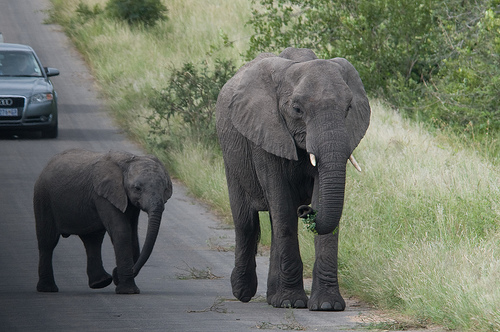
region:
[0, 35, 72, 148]
shiny silver audi driving on a paved road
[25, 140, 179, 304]
grey baby african elephant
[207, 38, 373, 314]
big grey african elephant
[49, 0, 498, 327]
tall light green grass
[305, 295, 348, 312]
grey curved elephant toes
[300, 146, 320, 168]
pointed white elephant tusk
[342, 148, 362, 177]
pointed white elephant tusk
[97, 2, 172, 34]
short green leafy bush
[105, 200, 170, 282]
baby elephant's wet trunk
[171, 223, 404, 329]
dead grass strewn on the road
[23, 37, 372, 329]
There are two elephants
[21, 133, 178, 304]
This is the smaller elephant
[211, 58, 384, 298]
This is the larger elephant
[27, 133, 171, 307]
Smaller elephant is in the middle of the road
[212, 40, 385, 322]
Larger elephant is on the side of the road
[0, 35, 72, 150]
Car behind the smaller elephant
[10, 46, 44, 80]
Man is driving the car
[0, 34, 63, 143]
The car is an Audi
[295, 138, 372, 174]
Bigger elephant has white tusks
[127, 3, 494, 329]
Grass next to side of road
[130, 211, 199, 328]
Elephant has long gray trunk.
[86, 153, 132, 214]
Elephant has large gray ear.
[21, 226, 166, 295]
Elephant is walking on road.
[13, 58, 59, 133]
Gray car behind elephants.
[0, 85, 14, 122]
Car is made by Audi.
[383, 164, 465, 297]
Tall grass on side of road.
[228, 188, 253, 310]
Elephant has large gray leg.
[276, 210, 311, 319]
Elephant has large gray leg.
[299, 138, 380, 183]
Elephant has white tusks.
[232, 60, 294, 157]
Elephant has large gray ear.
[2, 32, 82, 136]
an Audi car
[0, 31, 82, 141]
this car is manufactured by Audi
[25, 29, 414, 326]
two elephants in the road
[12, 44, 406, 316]
two African elephants in the road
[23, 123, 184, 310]
this elephant is very young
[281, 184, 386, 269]
a branch in the elephant's trunk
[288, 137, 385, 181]
the white tusks of an elephant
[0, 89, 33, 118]
the Audi logo and a license plate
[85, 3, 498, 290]
there is grass and brush on the side of the road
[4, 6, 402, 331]
the road and the elephants are grey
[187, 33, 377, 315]
elephant on a street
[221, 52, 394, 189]
head of an elephant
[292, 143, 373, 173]
trunks of an elephant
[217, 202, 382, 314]
legs of an elephant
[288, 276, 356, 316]
feet of an elephant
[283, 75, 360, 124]
eyes of an elephant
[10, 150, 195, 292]
a baby elephant on street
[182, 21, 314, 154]
body of an elephant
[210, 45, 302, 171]
ears of an elephant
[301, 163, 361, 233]
nose of an elephant